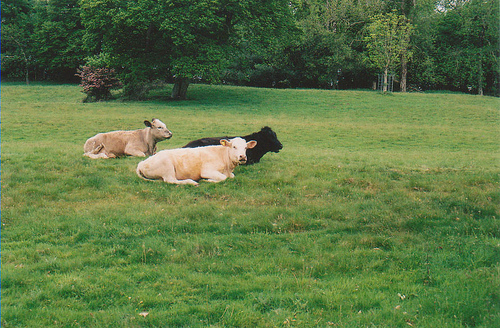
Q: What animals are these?
A: Cows.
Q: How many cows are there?
A: Three.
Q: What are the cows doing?
A: Laying.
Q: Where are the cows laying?
A: A field.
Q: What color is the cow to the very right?
A: Black.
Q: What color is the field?
A: Green.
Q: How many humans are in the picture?
A: None.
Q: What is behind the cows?
A: Trees.